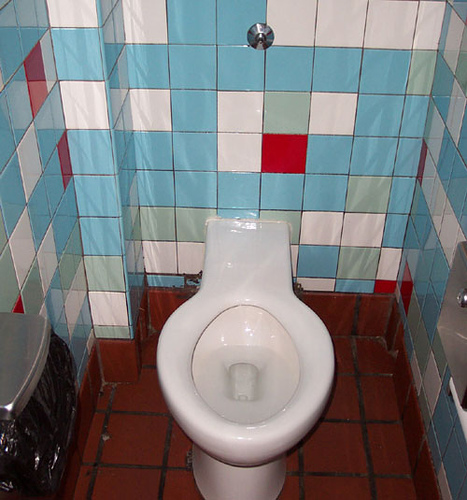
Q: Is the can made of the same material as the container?
A: Yes, both the can and the container are made of metal.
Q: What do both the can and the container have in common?
A: The material, both the can and the container are metallic.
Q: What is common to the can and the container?
A: The material, both the can and the container are metallic.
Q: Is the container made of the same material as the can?
A: Yes, both the container and the can are made of metal.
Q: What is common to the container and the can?
A: The material, both the container and the can are metallic.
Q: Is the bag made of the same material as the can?
A: No, the bag is made of plastic and the can is made of metal.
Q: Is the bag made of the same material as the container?
A: No, the bag is made of plastic and the container is made of metal.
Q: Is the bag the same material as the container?
A: No, the bag is made of plastic and the container is made of metal.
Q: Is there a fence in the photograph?
A: No, there are no fences.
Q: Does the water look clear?
A: Yes, the water is clear.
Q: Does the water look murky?
A: No, the water is clear.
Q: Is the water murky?
A: No, the water is clear.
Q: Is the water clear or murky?
A: The water is clear.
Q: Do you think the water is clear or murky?
A: The water is clear.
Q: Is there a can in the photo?
A: Yes, there is a can.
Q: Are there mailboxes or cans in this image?
A: Yes, there is a can.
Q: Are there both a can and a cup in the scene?
A: No, there is a can but no cups.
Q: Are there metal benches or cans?
A: Yes, there is a metal can.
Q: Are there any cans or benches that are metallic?
A: Yes, the can is metallic.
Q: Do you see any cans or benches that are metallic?
A: Yes, the can is metallic.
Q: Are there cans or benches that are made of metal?
A: Yes, the can is made of metal.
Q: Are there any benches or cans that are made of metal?
A: Yes, the can is made of metal.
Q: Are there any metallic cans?
A: Yes, there is a metal can.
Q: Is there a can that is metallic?
A: Yes, there is a can that is metallic.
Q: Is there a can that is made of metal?
A: Yes, there is a can that is made of metal.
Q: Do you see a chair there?
A: No, there are no chairs.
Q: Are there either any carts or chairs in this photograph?
A: No, there are no chairs or carts.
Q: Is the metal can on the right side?
A: No, the can is on the left of the image.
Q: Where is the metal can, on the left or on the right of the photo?
A: The can is on the left of the image.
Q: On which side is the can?
A: The can is on the left of the image.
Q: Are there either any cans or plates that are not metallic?
A: No, there is a can but it is metallic.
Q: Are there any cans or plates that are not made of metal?
A: No, there is a can but it is made of metal.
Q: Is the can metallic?
A: Yes, the can is metallic.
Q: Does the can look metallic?
A: Yes, the can is metallic.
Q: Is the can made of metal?
A: Yes, the can is made of metal.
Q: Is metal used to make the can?
A: Yes, the can is made of metal.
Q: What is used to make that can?
A: The can is made of metal.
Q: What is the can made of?
A: The can is made of metal.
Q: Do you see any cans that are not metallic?
A: No, there is a can but it is metallic.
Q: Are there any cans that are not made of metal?
A: No, there is a can but it is made of metal.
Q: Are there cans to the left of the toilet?
A: Yes, there is a can to the left of the toilet.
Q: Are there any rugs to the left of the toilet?
A: No, there is a can to the left of the toilet.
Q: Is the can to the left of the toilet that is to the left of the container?
A: Yes, the can is to the left of the toilet.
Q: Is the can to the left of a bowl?
A: No, the can is to the left of the toilet.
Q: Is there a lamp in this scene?
A: No, there are no lamps.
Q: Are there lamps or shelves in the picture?
A: No, there are no lamps or shelves.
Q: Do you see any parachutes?
A: No, there are no parachutes.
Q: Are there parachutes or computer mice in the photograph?
A: No, there are no parachutes or computer mice.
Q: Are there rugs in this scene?
A: No, there are no rugs.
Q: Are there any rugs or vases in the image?
A: No, there are no rugs or vases.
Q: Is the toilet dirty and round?
A: No, the toilet is round but clean.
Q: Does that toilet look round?
A: Yes, the toilet is round.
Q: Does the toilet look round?
A: Yes, the toilet is round.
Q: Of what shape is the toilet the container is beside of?
A: The toilet is round.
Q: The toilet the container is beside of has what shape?
A: The toilet is round.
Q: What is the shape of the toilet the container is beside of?
A: The toilet is round.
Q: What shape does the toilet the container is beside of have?
A: The toilet has round shape.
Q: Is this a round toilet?
A: Yes, this is a round toilet.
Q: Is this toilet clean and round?
A: Yes, the toilet is clean and round.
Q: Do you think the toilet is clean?
A: Yes, the toilet is clean.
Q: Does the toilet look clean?
A: Yes, the toilet is clean.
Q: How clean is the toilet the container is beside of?
A: The toilet is clean.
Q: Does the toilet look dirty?
A: No, the toilet is clean.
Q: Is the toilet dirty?
A: No, the toilet is clean.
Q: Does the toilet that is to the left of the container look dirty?
A: No, the toilet is clean.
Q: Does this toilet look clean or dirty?
A: The toilet is clean.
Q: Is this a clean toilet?
A: Yes, this is a clean toilet.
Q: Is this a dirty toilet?
A: No, this is a clean toilet.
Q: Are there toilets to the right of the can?
A: Yes, there is a toilet to the right of the can.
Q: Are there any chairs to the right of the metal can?
A: No, there is a toilet to the right of the can.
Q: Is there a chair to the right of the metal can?
A: No, there is a toilet to the right of the can.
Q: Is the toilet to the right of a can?
A: Yes, the toilet is to the right of a can.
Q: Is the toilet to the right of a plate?
A: No, the toilet is to the right of a can.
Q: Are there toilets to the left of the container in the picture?
A: Yes, there is a toilet to the left of the container.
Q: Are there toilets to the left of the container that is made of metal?
A: Yes, there is a toilet to the left of the container.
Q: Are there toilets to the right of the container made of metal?
A: No, the toilet is to the left of the container.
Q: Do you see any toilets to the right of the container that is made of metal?
A: No, the toilet is to the left of the container.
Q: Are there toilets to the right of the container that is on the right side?
A: No, the toilet is to the left of the container.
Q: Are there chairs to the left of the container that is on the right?
A: No, there is a toilet to the left of the container.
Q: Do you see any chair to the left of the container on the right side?
A: No, there is a toilet to the left of the container.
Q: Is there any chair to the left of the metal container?
A: No, there is a toilet to the left of the container.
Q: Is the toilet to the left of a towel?
A: No, the toilet is to the left of the container.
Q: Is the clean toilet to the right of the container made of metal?
A: No, the toilet is to the left of the container.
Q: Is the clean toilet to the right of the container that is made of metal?
A: No, the toilet is to the left of the container.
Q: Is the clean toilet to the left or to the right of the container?
A: The toilet is to the left of the container.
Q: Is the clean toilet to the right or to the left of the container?
A: The toilet is to the left of the container.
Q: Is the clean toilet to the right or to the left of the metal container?
A: The toilet is to the left of the container.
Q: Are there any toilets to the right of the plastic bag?
A: Yes, there is a toilet to the right of the bag.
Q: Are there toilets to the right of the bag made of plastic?
A: Yes, there is a toilet to the right of the bag.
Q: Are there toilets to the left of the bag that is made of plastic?
A: No, the toilet is to the right of the bag.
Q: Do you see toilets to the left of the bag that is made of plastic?
A: No, the toilet is to the right of the bag.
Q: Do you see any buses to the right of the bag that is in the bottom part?
A: No, there is a toilet to the right of the bag.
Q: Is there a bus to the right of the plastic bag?
A: No, there is a toilet to the right of the bag.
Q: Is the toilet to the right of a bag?
A: Yes, the toilet is to the right of a bag.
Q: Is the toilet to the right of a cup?
A: No, the toilet is to the right of a bag.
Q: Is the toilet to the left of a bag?
A: No, the toilet is to the right of a bag.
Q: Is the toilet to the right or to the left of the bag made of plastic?
A: The toilet is to the right of the bag.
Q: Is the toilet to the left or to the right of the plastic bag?
A: The toilet is to the right of the bag.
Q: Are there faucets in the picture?
A: No, there are no faucets.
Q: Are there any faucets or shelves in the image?
A: No, there are no faucets or shelves.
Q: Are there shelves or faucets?
A: No, there are no faucets or shelves.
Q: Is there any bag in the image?
A: Yes, there is a bag.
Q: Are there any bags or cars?
A: Yes, there is a bag.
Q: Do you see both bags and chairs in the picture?
A: No, there is a bag but no chairs.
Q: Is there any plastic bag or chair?
A: Yes, there is a plastic bag.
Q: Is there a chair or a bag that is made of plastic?
A: Yes, the bag is made of plastic.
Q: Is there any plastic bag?
A: Yes, there is a bag that is made of plastic.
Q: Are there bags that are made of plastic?
A: Yes, there is a bag that is made of plastic.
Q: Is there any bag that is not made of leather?
A: Yes, there is a bag that is made of plastic.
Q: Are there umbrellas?
A: No, there are no umbrellas.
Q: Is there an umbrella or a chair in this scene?
A: No, there are no umbrellas or chairs.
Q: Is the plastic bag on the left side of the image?
A: Yes, the bag is on the left of the image.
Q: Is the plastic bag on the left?
A: Yes, the bag is on the left of the image.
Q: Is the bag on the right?
A: No, the bag is on the left of the image.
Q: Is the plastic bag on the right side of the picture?
A: No, the bag is on the left of the image.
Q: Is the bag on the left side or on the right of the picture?
A: The bag is on the left of the image.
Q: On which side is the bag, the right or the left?
A: The bag is on the left of the image.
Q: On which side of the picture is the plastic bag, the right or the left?
A: The bag is on the left of the image.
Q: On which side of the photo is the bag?
A: The bag is on the left of the image.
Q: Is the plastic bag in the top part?
A: No, the bag is in the bottom of the image.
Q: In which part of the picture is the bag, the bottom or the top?
A: The bag is in the bottom of the image.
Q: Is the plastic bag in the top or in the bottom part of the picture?
A: The bag is in the bottom of the image.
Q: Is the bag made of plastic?
A: Yes, the bag is made of plastic.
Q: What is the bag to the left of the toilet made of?
A: The bag is made of plastic.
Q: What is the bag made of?
A: The bag is made of plastic.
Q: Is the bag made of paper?
A: No, the bag is made of plastic.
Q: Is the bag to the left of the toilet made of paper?
A: No, the bag is made of plastic.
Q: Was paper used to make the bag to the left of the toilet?
A: No, the bag is made of plastic.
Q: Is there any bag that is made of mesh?
A: No, there is a bag but it is made of plastic.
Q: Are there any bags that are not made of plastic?
A: No, there is a bag but it is made of plastic.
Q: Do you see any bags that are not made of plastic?
A: No, there is a bag but it is made of plastic.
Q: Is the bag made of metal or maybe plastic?
A: The bag is made of plastic.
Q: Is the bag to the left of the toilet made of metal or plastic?
A: The bag is made of plastic.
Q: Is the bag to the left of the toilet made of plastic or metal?
A: The bag is made of plastic.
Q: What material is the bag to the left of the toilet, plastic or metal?
A: The bag is made of plastic.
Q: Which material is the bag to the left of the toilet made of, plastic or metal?
A: The bag is made of plastic.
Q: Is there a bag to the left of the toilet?
A: Yes, there is a bag to the left of the toilet.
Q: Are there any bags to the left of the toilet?
A: Yes, there is a bag to the left of the toilet.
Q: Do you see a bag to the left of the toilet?
A: Yes, there is a bag to the left of the toilet.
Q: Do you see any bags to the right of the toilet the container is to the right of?
A: No, the bag is to the left of the toilet.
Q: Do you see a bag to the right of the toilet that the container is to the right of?
A: No, the bag is to the left of the toilet.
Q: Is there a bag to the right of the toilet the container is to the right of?
A: No, the bag is to the left of the toilet.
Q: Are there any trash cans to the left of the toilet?
A: No, there is a bag to the left of the toilet.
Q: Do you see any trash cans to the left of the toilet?
A: No, there is a bag to the left of the toilet.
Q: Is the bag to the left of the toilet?
A: Yes, the bag is to the left of the toilet.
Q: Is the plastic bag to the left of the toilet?
A: Yes, the bag is to the left of the toilet.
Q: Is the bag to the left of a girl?
A: No, the bag is to the left of the toilet.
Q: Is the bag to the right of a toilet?
A: No, the bag is to the left of a toilet.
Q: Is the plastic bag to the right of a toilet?
A: No, the bag is to the left of a toilet.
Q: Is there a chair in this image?
A: No, there are no chairs.